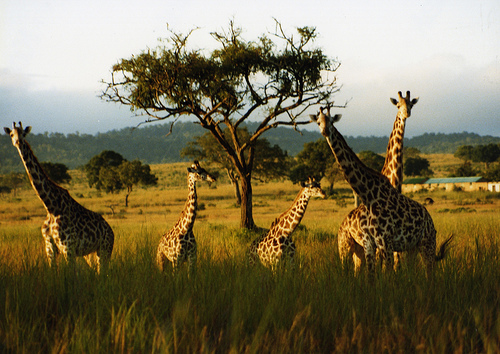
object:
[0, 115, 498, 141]
horizon line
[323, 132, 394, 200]
necks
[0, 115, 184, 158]
green hills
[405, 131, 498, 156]
green hills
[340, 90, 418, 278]
giraffe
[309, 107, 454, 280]
giraffe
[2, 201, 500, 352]
grass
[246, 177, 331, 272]
giraffe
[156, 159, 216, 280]
giraffe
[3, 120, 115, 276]
giraffe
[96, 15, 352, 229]
tree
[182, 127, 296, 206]
tree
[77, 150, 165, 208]
tree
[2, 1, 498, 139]
sky